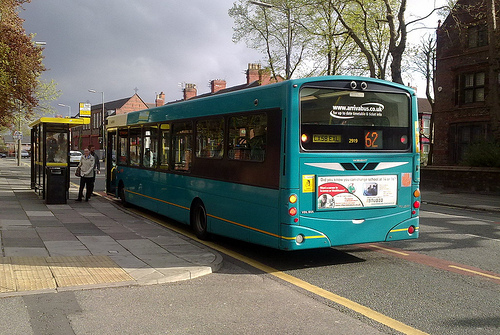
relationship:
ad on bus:
[318, 175, 397, 210] [102, 76, 420, 251]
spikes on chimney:
[241, 68, 246, 75] [245, 61, 261, 85]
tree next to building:
[378, 2, 450, 87] [430, 0, 500, 166]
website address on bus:
[330, 100, 386, 120] [102, 76, 420, 251]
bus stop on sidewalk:
[28, 116, 86, 204] [2, 159, 221, 297]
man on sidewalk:
[74, 150, 97, 201] [2, 159, 221, 297]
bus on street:
[102, 76, 420, 251] [16, 156, 498, 334]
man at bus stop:
[74, 150, 97, 201] [28, 116, 86, 204]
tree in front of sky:
[378, 2, 450, 87] [7, 2, 452, 114]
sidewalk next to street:
[2, 159, 221, 297] [16, 156, 498, 334]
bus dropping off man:
[102, 76, 420, 251] [74, 150, 97, 201]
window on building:
[461, 72, 485, 102] [430, 0, 500, 166]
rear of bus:
[288, 76, 418, 251] [102, 76, 420, 251]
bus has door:
[102, 76, 420, 251] [108, 131, 117, 194]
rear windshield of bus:
[298, 86, 410, 128] [102, 76, 420, 251]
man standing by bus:
[74, 150, 97, 201] [102, 76, 420, 251]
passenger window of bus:
[128, 126, 141, 168] [102, 76, 420, 251]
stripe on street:
[72, 181, 422, 334] [16, 156, 498, 334]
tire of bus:
[191, 198, 210, 239] [102, 76, 420, 251]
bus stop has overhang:
[28, 116, 86, 204] [27, 118, 91, 128]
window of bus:
[142, 127, 157, 167] [102, 76, 420, 251]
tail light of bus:
[288, 206, 297, 216] [102, 76, 420, 251]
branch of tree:
[401, 4, 449, 28] [378, 2, 450, 87]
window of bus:
[172, 119, 193, 172] [102, 76, 420, 251]